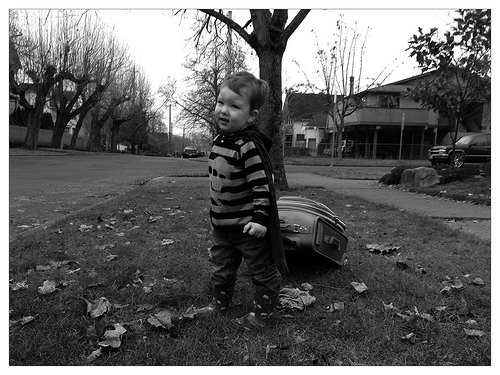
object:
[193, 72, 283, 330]
boy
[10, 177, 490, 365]
grass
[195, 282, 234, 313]
boot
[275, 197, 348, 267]
suitcase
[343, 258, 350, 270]
wheel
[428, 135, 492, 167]
suv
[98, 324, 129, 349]
leaf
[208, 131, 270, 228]
sweater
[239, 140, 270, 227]
sleeve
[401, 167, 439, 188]
boulder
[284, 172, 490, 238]
sidewalk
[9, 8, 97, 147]
tree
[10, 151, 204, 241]
street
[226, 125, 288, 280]
cape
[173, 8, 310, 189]
tree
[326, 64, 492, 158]
house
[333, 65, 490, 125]
upper deck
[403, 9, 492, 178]
tree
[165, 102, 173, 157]
telephone pole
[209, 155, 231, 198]
skull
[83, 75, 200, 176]
distance